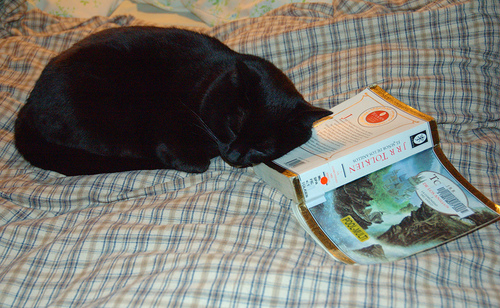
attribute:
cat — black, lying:
[14, 23, 332, 178]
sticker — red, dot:
[319, 175, 329, 184]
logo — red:
[365, 109, 390, 125]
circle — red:
[365, 106, 389, 123]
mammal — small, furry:
[11, 17, 342, 205]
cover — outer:
[324, 120, 495, 265]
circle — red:
[317, 170, 330, 184]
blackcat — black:
[13, 25, 329, 176]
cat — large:
[18, 15, 347, 170]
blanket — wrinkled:
[83, 212, 248, 277]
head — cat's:
[197, 63, 348, 178]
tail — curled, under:
[7, 102, 164, 177]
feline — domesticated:
[11, 24, 333, 176]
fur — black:
[41, 32, 220, 141]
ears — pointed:
[230, 58, 340, 120]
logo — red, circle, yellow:
[358, 104, 395, 129]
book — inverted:
[306, 115, 476, 244]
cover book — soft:
[262, 84, 425, 174]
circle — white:
[356, 104, 396, 132]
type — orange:
[370, 110, 383, 124]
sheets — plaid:
[3, 4, 498, 304]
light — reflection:
[2, 0, 281, 91]